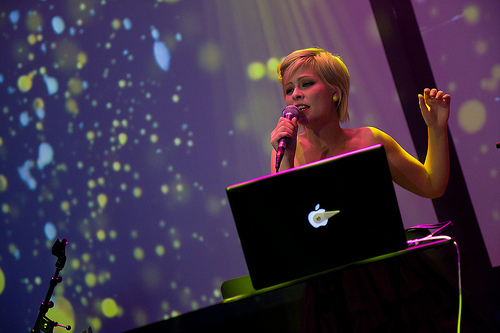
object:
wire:
[408, 235, 464, 331]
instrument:
[33, 237, 76, 331]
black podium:
[116, 236, 463, 331]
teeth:
[294, 104, 307, 107]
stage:
[0, 0, 496, 332]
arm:
[361, 126, 450, 199]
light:
[362, 122, 434, 176]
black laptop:
[226, 141, 405, 292]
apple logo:
[307, 203, 341, 228]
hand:
[269, 117, 296, 152]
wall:
[2, 0, 220, 332]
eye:
[300, 80, 316, 87]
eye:
[285, 87, 294, 94]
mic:
[273, 103, 299, 172]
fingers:
[418, 94, 432, 115]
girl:
[266, 46, 454, 200]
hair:
[280, 46, 349, 121]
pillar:
[372, 0, 499, 333]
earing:
[333, 96, 339, 101]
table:
[127, 237, 469, 331]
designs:
[0, 0, 499, 331]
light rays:
[224, 0, 332, 60]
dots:
[30, 96, 44, 122]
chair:
[217, 278, 257, 300]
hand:
[416, 88, 451, 126]